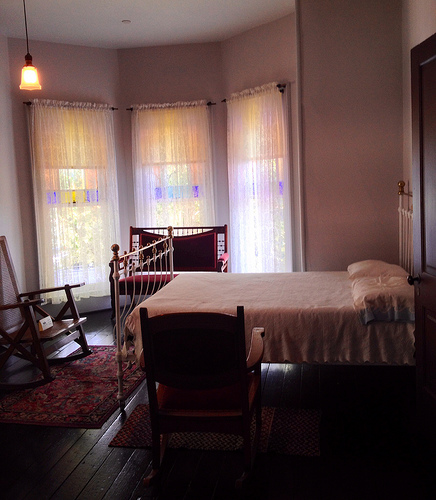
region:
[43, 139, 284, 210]
three stained glass windows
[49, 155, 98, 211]
stained glass through curtains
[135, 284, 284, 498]
wooden rocking chair by the bed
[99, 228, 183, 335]
metal bed frame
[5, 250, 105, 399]
wooden rocking chair by the foot of the bed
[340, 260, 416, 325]
two pillows on the bed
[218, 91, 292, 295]
ling white sheer curtain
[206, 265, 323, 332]
white sheet on a bed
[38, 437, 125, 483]
dark wooden slat floor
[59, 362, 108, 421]
ornate rug at the foot of the bed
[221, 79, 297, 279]
white curtain in front of window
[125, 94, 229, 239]
white curtain in front of window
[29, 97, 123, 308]
white curtain in front of window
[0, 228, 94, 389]
rocking chair made of wood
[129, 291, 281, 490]
chair made of wood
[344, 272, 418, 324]
pillow on a bed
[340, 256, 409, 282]
pillow on a bed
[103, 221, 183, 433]
wire foot board of a bed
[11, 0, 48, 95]
light hanging from ceiling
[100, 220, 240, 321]
chair with red upholstery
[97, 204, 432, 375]
a twin bed with white sheets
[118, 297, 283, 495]
a wooden rocking chair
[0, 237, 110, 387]
a wooden rocking chair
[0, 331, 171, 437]
a piece of carpet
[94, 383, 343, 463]
a piece of carpet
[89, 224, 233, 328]
a small sofa made of wood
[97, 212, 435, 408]
a bed with a cradle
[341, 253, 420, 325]
two pillows on bed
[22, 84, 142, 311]
a white window curtain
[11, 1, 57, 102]
a light lamp hanged on the roof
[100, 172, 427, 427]
bed with metal frame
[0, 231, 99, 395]
wooden rocking chair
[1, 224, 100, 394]
high back rocking chair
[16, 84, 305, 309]
three tall windows with light curtains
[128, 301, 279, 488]
red upholstered wooden rocking chair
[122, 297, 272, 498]
short wooden rocking chair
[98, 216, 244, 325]
red upholstered indoor bench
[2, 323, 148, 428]
large rug at food of bed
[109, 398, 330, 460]
small rug on the side of bed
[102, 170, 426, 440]
bed with a white blanket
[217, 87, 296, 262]
A beautiful wall curtain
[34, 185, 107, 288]
A beautiful wall curtain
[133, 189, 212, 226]
A beautiful wall curtain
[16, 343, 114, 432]
A brown carpet floor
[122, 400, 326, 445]
A brown carpet floor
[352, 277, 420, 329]
A white and blue pillow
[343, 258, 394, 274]
A white and blue pillow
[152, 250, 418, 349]
A well spread bed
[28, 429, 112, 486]
A white and blue pillow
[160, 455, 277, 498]
A white and blue pillow